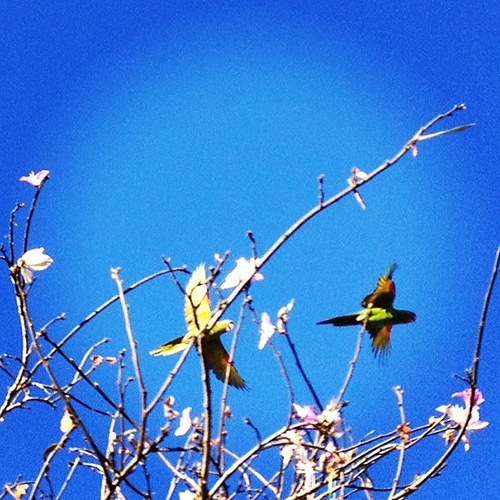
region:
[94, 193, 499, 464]
birds that are flying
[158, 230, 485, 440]
birds flying outside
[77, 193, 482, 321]
two birds flying outside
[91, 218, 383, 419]
two small bird outside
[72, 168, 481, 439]
two small birds flying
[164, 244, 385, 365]
two small birds flying outside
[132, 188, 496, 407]
two small birds flying together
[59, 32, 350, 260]
a blue sky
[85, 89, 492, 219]
a sky that is blue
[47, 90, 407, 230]
a blue sky outside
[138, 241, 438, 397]
two birds flying in air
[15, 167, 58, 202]
pink flower on stem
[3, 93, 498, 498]
tree branches with pink flowers on them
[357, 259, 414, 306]
wing on bird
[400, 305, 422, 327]
head of bird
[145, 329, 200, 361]
tail of bird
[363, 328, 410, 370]
feathers on bird wing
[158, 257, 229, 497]
brown branch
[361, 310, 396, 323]
green feathers on chest of bird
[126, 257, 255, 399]
yellow bird flying in air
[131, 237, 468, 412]
two birds resting on branch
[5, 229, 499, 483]
branches have pink and white flowers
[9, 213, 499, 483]
branches have no leaves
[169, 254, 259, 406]
bird has wings outstretched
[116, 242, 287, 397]
bird feathers are yellow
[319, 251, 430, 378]
bird is green, brown and black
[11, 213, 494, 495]
bare branches are brown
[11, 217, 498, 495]
sunlight shining on branches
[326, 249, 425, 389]
bird holding onto branch with tallons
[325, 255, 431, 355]
brown bird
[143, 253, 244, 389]
yellow bird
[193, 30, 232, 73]
white clouds in blue sky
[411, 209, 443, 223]
white clouds in blue sky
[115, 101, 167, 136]
white clouds in blue sky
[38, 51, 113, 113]
white clouds in blue sky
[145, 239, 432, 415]
two birds with wings expanded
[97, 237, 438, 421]
two birds on tree branches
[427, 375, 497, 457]
small pink flowers on branches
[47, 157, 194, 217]
bright clear blue sky with no clouds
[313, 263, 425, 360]
bird with yellow and black feathers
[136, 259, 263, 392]
bird with yellow feathers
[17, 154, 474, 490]
branches with pink flowers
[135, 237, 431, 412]
two birds about to fly away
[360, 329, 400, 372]
feathers on wings